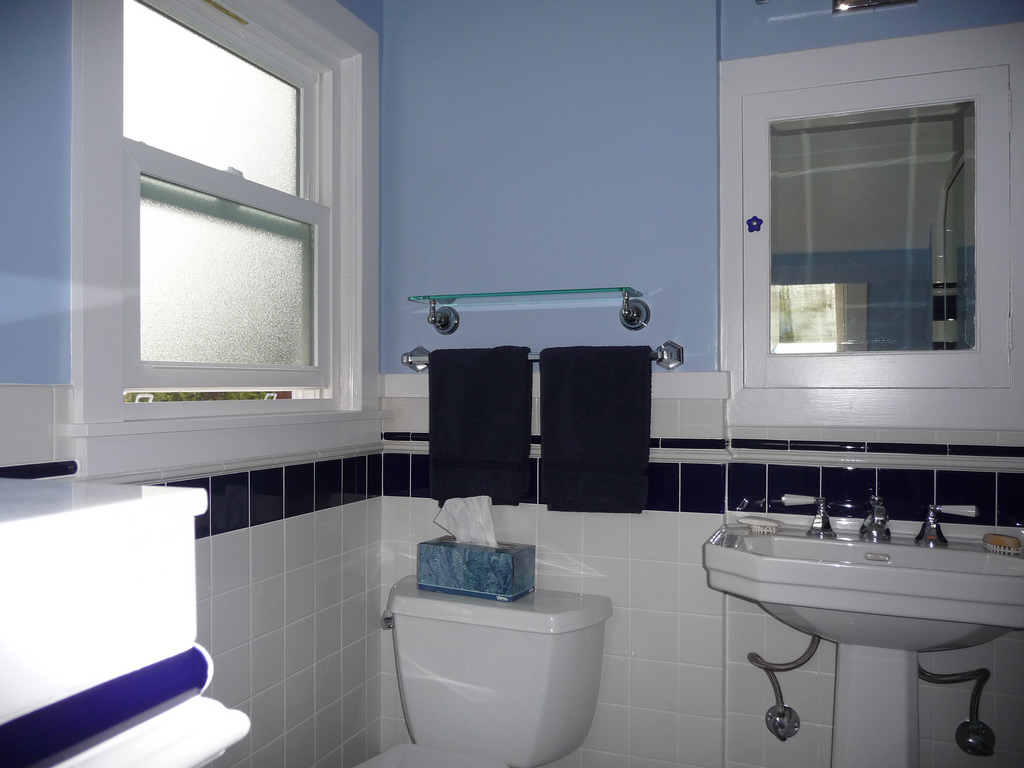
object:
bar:
[0, 634, 250, 765]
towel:
[427, 344, 533, 507]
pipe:
[747, 637, 824, 709]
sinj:
[703, 508, 1024, 768]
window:
[128, 0, 328, 372]